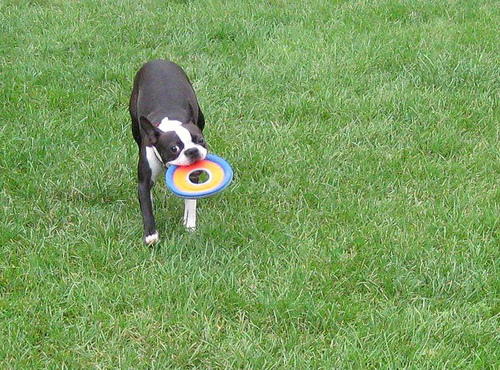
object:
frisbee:
[165, 154, 233, 198]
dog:
[129, 62, 204, 246]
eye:
[170, 145, 180, 153]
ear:
[139, 116, 164, 146]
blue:
[205, 155, 233, 195]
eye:
[197, 137, 203, 143]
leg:
[183, 199, 196, 232]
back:
[138, 61, 198, 129]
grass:
[0, 0, 499, 370]